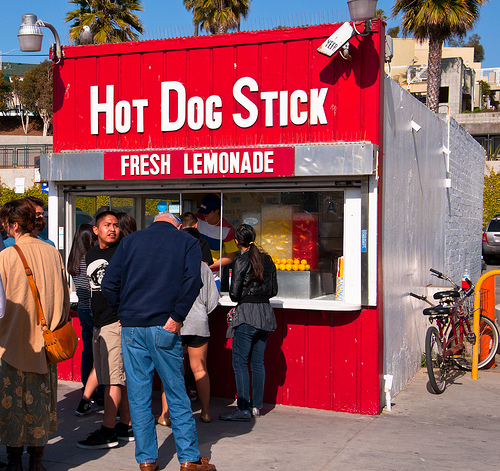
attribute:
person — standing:
[121, 209, 200, 470]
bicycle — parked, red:
[413, 267, 498, 395]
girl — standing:
[228, 223, 276, 420]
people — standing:
[2, 212, 278, 469]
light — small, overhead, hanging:
[19, 11, 64, 71]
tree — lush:
[425, 0, 444, 108]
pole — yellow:
[474, 277, 480, 384]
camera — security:
[316, 24, 353, 64]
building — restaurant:
[54, 45, 379, 386]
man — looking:
[91, 211, 121, 244]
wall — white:
[383, 142, 480, 274]